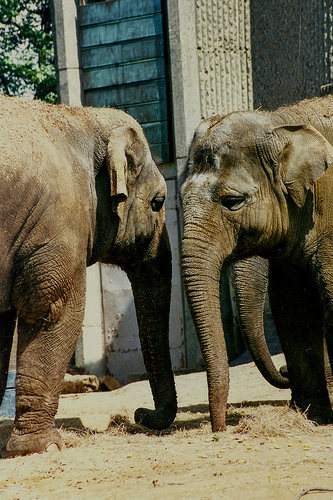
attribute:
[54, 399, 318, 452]
hay — dry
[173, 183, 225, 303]
skin — wrinkled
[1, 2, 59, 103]
tree — green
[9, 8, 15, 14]
leaves — green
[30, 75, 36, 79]
leaves — green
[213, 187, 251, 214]
eye — large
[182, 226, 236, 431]
trunk — curved, gray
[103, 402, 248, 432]
shadow — dark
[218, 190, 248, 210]
eye — black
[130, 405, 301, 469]
dirt — light brown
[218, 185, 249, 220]
eye — open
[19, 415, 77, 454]
foot — gray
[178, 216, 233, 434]
trunk — long, gray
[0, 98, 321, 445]
elephants — gray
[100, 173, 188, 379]
door — metal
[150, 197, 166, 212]
eye — black